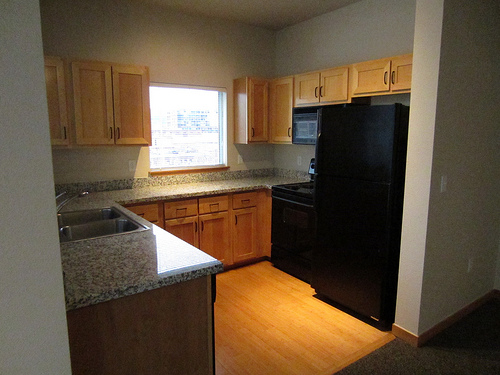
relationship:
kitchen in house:
[108, 131, 319, 294] [82, 44, 469, 322]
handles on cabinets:
[172, 200, 218, 235] [187, 198, 268, 250]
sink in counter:
[68, 207, 145, 265] [86, 197, 171, 311]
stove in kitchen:
[288, 177, 313, 196] [108, 131, 319, 294]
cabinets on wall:
[187, 198, 268, 250] [409, 49, 494, 265]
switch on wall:
[429, 167, 462, 212] [409, 49, 494, 265]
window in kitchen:
[147, 88, 198, 154] [108, 131, 319, 294]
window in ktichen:
[147, 88, 198, 154] [111, 133, 338, 343]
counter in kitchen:
[86, 197, 171, 311] [108, 131, 319, 294]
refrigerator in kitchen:
[321, 108, 398, 286] [108, 131, 319, 294]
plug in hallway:
[464, 263, 479, 290] [467, 196, 493, 256]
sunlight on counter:
[149, 166, 186, 178] [86, 197, 171, 311]